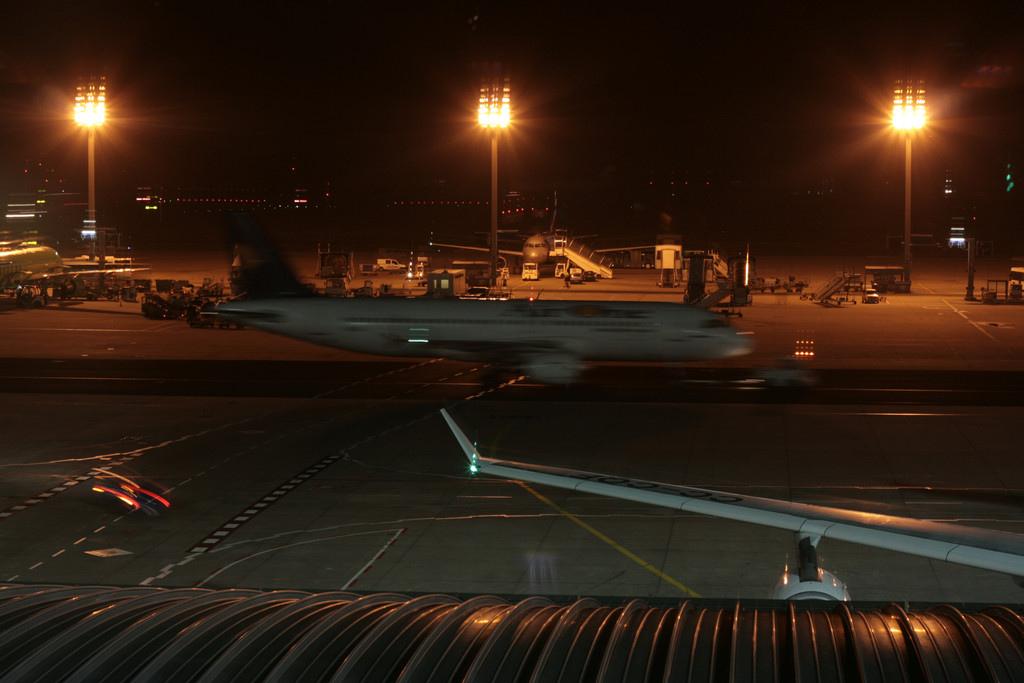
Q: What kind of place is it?
A: It is an airport.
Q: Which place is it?
A: It is an airport.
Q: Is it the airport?
A: Yes, it is the airport.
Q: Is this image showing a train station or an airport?
A: It is showing an airport.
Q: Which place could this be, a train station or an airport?
A: It is an airport.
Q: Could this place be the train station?
A: No, it is the airport.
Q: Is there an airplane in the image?
A: Yes, there is an airplane.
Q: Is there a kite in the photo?
A: No, there are no kites.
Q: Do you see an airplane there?
A: Yes, there is an airplane.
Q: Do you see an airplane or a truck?
A: Yes, there is an airplane.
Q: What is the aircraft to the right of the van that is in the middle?
A: The aircraft is an airplane.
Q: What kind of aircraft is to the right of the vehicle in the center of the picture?
A: The aircraft is an airplane.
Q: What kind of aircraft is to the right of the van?
A: The aircraft is an airplane.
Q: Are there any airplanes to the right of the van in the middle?
A: Yes, there is an airplane to the right of the van.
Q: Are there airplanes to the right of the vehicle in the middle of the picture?
A: Yes, there is an airplane to the right of the van.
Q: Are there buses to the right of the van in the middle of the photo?
A: No, there is an airplane to the right of the van.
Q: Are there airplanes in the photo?
A: Yes, there is an airplane.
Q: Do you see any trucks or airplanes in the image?
A: Yes, there is an airplane.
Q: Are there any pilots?
A: No, there are no pilots.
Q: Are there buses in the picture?
A: No, there are no buses.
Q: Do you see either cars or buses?
A: No, there are no buses or cars.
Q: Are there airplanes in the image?
A: Yes, there is an airplane.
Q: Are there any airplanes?
A: Yes, there is an airplane.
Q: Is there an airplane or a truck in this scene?
A: Yes, there is an airplane.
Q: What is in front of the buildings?
A: The airplane is in front of the buildings.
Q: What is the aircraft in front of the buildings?
A: The aircraft is an airplane.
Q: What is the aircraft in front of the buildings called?
A: The aircraft is an airplane.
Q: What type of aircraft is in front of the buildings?
A: The aircraft is an airplane.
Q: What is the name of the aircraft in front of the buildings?
A: The aircraft is an airplane.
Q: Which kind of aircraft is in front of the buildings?
A: The aircraft is an airplane.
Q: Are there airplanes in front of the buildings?
A: Yes, there is an airplane in front of the buildings.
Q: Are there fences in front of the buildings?
A: No, there is an airplane in front of the buildings.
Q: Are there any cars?
A: No, there are no cars.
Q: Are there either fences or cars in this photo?
A: No, there are no cars or fences.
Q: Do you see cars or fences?
A: No, there are no cars or fences.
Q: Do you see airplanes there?
A: Yes, there is an airplane.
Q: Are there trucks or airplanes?
A: Yes, there is an airplane.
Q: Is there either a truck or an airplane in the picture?
A: Yes, there is an airplane.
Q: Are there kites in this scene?
A: No, there are no kites.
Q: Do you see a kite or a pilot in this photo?
A: No, there are no kites or pilots.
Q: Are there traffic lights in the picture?
A: No, there are no traffic lights.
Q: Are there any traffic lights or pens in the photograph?
A: No, there are no traffic lights or pens.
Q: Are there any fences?
A: No, there are no fences.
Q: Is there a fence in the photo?
A: No, there are no fences.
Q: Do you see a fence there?
A: No, there are no fences.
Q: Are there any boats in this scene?
A: No, there are no boats.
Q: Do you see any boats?
A: No, there are no boats.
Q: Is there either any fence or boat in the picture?
A: No, there are no boats or fences.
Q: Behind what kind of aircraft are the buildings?
A: The buildings are behind the plane.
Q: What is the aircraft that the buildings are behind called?
A: The aircraft is an airplane.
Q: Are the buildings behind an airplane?
A: Yes, the buildings are behind an airplane.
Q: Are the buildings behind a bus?
A: No, the buildings are behind an airplane.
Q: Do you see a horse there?
A: No, there are no horses.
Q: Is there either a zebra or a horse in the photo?
A: No, there are no horses or zebras.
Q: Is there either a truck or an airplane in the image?
A: Yes, there is an airplane.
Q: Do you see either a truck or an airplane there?
A: Yes, there is an airplane.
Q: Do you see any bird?
A: No, there are no birds.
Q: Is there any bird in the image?
A: No, there are no birds.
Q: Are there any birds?
A: No, there are no birds.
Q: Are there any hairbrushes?
A: No, there are no hairbrushes.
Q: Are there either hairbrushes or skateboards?
A: No, there are no hairbrushes or skateboards.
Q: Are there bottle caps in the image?
A: No, there are no bottle caps.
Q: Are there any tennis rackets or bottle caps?
A: No, there are no bottle caps or tennis rackets.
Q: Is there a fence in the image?
A: No, there are no fences.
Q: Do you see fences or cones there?
A: No, there are no fences or cones.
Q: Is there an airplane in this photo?
A: Yes, there is an airplane.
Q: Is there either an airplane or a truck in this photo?
A: Yes, there is an airplane.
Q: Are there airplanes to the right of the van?
A: Yes, there is an airplane to the right of the van.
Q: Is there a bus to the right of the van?
A: No, there is an airplane to the right of the van.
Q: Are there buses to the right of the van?
A: No, there is an airplane to the right of the van.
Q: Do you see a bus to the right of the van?
A: No, there is an airplane to the right of the van.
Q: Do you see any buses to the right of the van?
A: No, there is an airplane to the right of the van.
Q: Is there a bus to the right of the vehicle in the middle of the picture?
A: No, there is an airplane to the right of the van.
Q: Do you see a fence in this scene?
A: No, there are no fences.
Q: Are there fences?
A: No, there are no fences.